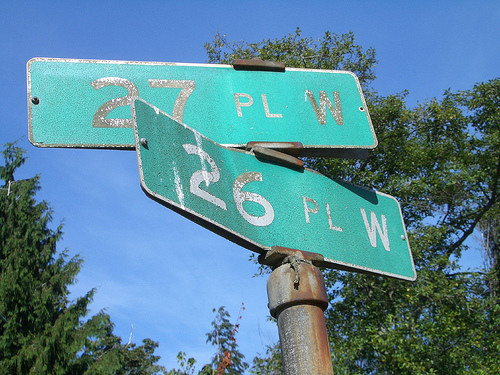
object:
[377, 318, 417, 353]
leaf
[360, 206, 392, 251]
white "w"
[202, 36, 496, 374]
tree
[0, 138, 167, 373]
tree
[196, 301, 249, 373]
tree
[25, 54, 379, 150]
sign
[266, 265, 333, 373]
pole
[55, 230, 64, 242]
leaf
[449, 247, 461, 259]
leaf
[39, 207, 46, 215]
leaf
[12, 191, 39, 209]
leaves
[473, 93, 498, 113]
leaves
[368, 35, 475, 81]
sky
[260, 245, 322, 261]
metal tab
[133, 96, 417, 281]
sign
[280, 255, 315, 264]
rust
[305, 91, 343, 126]
lettering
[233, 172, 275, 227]
number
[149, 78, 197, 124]
number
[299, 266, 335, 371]
stain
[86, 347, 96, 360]
leaf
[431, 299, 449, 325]
leaves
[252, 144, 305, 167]
clips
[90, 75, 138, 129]
numbers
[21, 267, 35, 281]
leaves